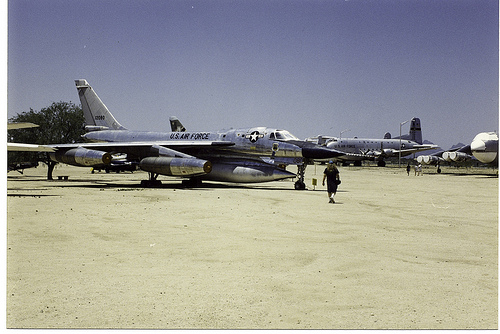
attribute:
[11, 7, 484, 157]
sky — blue, clear